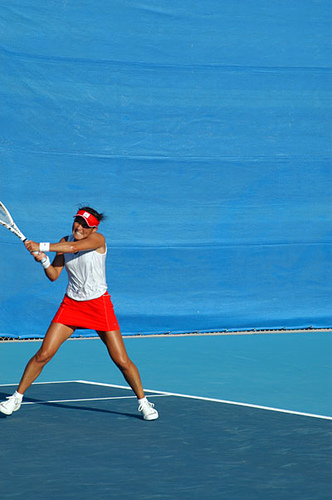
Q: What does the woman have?
A: A tennis racket.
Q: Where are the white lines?
A: On the court.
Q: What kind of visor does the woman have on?
A: Red.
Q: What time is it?
A: Afternoon.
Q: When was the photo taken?
A: During the daytime.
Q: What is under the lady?
A: The court.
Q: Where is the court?
A: On the ground.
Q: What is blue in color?
A: The ground.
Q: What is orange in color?
A: The skirt.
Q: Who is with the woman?
A: No people.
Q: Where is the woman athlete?
A: On a blue tennis court.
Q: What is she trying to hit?
A: A ball.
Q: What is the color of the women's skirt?
A: Red.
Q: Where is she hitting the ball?
A: To the other player.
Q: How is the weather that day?
A: Warm.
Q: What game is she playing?
A: Tennis.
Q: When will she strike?
A: When the ball comes.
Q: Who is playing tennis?
A: A women.